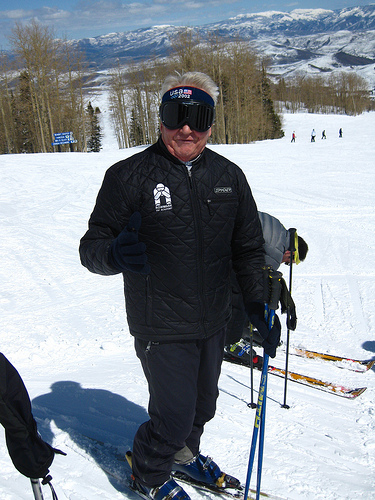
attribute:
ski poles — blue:
[240, 260, 274, 498]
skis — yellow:
[225, 319, 372, 401]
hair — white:
[159, 62, 225, 107]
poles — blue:
[243, 265, 281, 499]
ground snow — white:
[1, 111, 371, 498]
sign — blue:
[47, 129, 82, 148]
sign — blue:
[50, 130, 76, 145]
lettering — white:
[56, 134, 65, 142]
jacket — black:
[79, 135, 268, 350]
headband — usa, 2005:
[162, 84, 221, 120]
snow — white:
[7, 165, 68, 264]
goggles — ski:
[157, 100, 215, 131]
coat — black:
[80, 135, 270, 341]